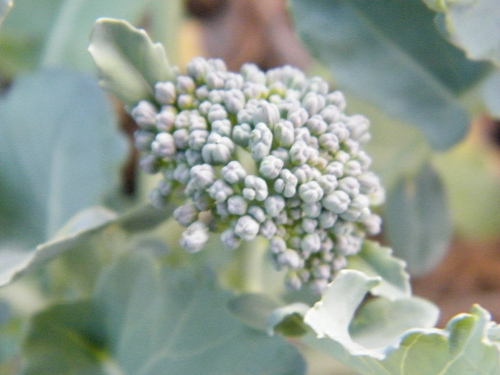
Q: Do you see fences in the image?
A: No, there are no fences.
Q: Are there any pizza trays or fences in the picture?
A: No, there are no fences or pizza trays.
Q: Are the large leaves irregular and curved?
A: Yes, the leaves are irregular and curved.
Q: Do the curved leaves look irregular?
A: Yes, the leaves are irregular.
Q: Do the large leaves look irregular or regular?
A: The leaves are irregular.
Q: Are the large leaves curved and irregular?
A: Yes, the leaves are curved and irregular.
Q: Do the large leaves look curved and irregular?
A: Yes, the leaves are curved and irregular.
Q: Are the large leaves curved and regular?
A: No, the leaves are curved but irregular.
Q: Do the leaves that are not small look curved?
A: Yes, the leaves are curved.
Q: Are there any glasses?
A: No, there are no glasses.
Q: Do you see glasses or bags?
A: No, there are no glasses or bags.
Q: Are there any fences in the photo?
A: No, there are no fences.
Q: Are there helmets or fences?
A: No, there are no fences or helmets.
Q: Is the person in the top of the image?
A: Yes, the person is in the top of the image.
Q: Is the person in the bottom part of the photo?
A: No, the person is in the top of the image.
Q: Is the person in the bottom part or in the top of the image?
A: The person is in the top of the image.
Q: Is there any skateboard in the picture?
A: No, there are no skateboards.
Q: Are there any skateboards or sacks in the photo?
A: No, there are no skateboards or sacks.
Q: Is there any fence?
A: No, there are no fences.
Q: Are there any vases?
A: No, there are no vases.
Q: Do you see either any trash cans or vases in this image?
A: No, there are no vases or trash cans.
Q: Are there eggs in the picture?
A: No, there are no eggs.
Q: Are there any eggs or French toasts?
A: No, there are no eggs or French toasts.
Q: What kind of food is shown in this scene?
A: The food is a vegetable.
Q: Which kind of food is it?
A: The food is a vegetable.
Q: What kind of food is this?
A: This is a vegetable.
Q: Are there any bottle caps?
A: No, there are no bottle caps.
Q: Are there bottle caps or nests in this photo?
A: No, there are no bottle caps or nests.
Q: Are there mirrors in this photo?
A: No, there are no mirrors.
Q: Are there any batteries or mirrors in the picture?
A: No, there are no mirrors or batteries.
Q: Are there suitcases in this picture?
A: No, there are no suitcases.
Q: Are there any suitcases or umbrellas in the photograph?
A: No, there are no suitcases or umbrellas.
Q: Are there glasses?
A: No, there are no glasses.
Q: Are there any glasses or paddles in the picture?
A: No, there are no glasses or paddles.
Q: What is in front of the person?
A: The plant is in front of the person.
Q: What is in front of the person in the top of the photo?
A: The plant is in front of the person.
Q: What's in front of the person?
A: The plant is in front of the person.